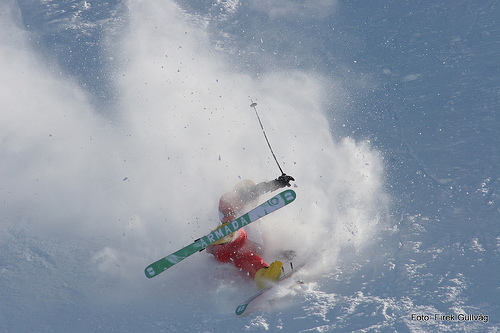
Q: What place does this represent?
A: It represents the field.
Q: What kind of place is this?
A: It is a field.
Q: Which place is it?
A: It is a field.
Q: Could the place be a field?
A: Yes, it is a field.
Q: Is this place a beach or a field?
A: It is a field.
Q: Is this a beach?
A: No, it is a field.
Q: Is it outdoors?
A: Yes, it is outdoors.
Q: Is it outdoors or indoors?
A: It is outdoors.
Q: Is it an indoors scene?
A: No, it is outdoors.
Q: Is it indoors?
A: No, it is outdoors.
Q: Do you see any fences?
A: No, there are no fences.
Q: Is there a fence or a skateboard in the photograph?
A: No, there are no fences or skateboards.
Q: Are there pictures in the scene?
A: No, there are no pictures.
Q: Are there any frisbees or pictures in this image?
A: No, there are no pictures or frisbees.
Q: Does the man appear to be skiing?
A: Yes, the man is skiing.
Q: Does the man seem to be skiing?
A: Yes, the man is skiing.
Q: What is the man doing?
A: The man is skiing.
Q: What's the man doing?
A: The man is skiing.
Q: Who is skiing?
A: The man is skiing.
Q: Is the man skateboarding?
A: No, the man is skiing.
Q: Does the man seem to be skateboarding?
A: No, the man is skiing.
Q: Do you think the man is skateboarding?
A: No, the man is skiing.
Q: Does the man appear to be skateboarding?
A: No, the man is skiing.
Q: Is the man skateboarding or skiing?
A: The man is skiing.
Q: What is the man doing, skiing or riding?
A: The man is skiing.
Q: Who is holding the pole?
A: The man is holding the pole.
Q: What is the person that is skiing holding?
A: The man is holding the pole.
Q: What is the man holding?
A: The man is holding the pole.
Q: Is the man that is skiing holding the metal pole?
A: Yes, the man is holding the pole.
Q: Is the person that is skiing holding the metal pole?
A: Yes, the man is holding the pole.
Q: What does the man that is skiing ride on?
A: The man rides on the ski.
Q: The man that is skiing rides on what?
A: The man rides on the ski.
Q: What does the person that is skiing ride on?
A: The man rides on the ski.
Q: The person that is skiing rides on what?
A: The man rides on the ski.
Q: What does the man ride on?
A: The man rides on the ski.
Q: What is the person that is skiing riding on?
A: The man is riding on the ski.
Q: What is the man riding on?
A: The man is riding on the ski.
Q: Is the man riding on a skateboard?
A: No, the man is riding on the ski.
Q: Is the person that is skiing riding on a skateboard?
A: No, the man is riding on the ski.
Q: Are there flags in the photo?
A: No, there are no flags.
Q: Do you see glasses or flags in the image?
A: No, there are no flags or glasses.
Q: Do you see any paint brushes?
A: No, there are no paint brushes.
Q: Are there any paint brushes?
A: No, there are no paint brushes.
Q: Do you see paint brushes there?
A: No, there are no paint brushes.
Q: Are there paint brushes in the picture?
A: No, there are no paint brushes.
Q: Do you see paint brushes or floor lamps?
A: No, there are no paint brushes or floor lamps.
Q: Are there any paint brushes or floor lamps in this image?
A: No, there are no paint brushes or floor lamps.